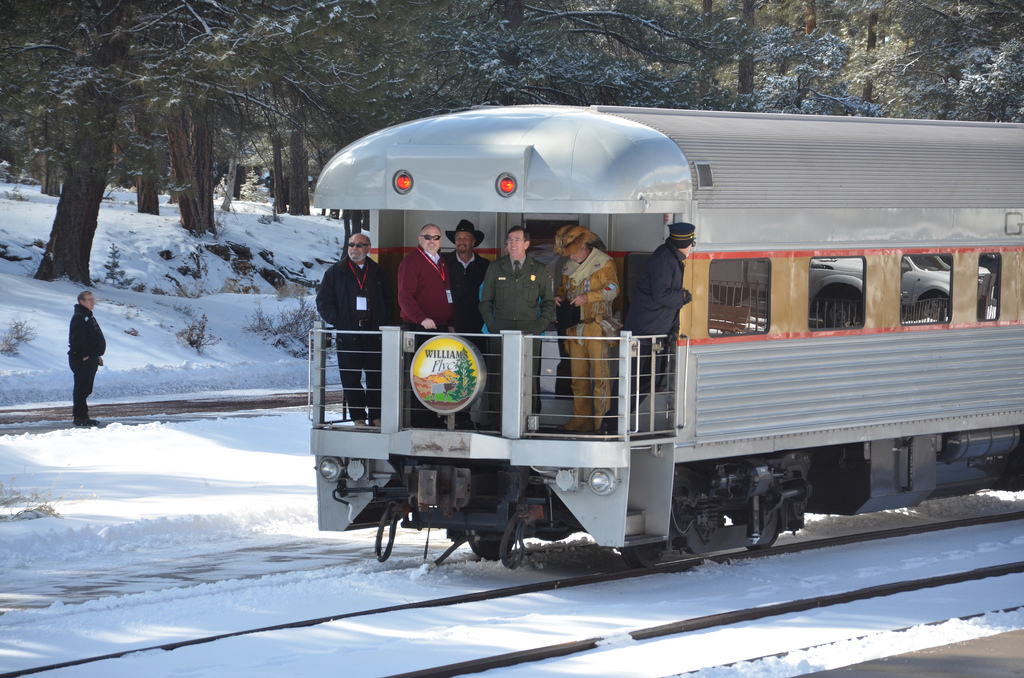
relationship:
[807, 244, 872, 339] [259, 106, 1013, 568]
window of train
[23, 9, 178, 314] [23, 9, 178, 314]
green leaves on tree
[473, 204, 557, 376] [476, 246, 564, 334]
badge on jacket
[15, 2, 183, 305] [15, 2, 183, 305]
leaves on tree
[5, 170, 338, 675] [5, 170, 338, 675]
snow on trees